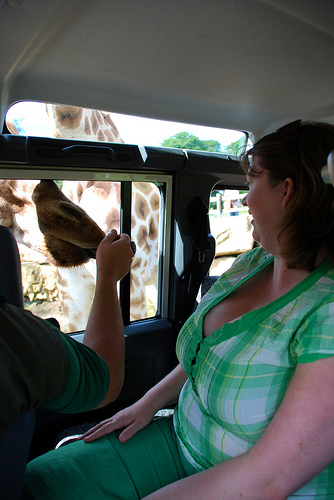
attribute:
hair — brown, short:
[238, 118, 333, 271]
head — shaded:
[19, 180, 107, 283]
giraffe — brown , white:
[28, 92, 178, 284]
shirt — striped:
[172, 248, 327, 497]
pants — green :
[24, 428, 181, 495]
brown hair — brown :
[242, 114, 333, 271]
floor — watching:
[133, 76, 198, 107]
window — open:
[1, 167, 183, 341]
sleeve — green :
[36, 315, 108, 411]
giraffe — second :
[20, 104, 166, 317]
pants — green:
[54, 433, 147, 484]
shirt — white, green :
[161, 239, 329, 494]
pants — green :
[24, 411, 200, 498]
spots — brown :
[131, 189, 154, 236]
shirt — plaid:
[169, 243, 333, 480]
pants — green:
[19, 406, 181, 497]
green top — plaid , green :
[179, 313, 322, 498]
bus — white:
[1, 0, 332, 498]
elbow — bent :
[95, 372, 125, 412]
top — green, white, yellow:
[174, 245, 332, 470]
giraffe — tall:
[8, 106, 178, 325]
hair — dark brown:
[241, 119, 321, 275]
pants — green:
[19, 417, 186, 496]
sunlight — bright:
[13, 106, 241, 152]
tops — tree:
[165, 129, 221, 149]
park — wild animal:
[8, 117, 258, 331]